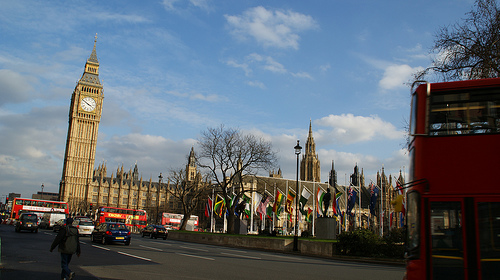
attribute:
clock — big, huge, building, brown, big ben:
[65, 42, 96, 206]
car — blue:
[90, 220, 141, 251]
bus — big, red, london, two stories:
[404, 77, 491, 277]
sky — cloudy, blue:
[142, 13, 282, 66]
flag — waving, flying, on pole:
[202, 188, 221, 219]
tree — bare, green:
[191, 139, 297, 226]